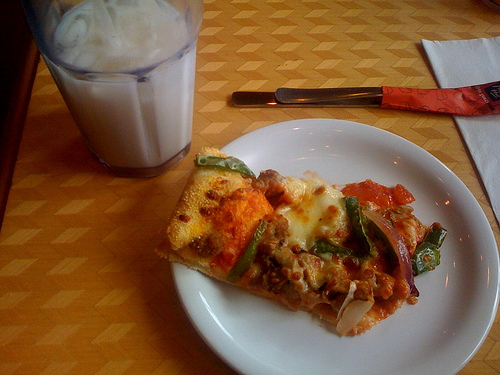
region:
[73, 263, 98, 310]
top of a table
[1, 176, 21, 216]
edge of a table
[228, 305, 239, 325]
side of a plate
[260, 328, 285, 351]
part of a plate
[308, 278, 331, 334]
part of a pizza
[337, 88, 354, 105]
part of a fork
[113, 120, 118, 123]
side of a glass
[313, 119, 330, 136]
side of a plate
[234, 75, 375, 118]
The handles to the utensils on the table.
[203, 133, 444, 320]
The green peppers on the pizza.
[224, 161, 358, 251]
The cheese on the pizza.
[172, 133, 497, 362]
The white plate the pizza is on.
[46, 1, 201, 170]
The glass on the table.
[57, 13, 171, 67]
The ice cubes in the drink.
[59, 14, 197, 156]
The milk in the cup.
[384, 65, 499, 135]
The red paper around the utensils.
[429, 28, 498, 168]
The white napkin the utensils are placed on.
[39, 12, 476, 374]
The table the items are on.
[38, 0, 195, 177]
a glass of milk with ice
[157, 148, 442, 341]
a slice of pizza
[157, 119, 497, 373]
pizza on a white plate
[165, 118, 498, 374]
a piece of pizza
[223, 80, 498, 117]
utensils wrapped in red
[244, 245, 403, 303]
a topping of meat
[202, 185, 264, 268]
a bubble of crust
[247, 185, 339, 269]
cheese on the pizza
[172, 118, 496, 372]
a white ceramic saucer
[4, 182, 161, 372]
a mosaic table top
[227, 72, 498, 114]
silverware wrapped in a red napkin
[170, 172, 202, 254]
the crust of a pizza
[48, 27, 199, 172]
a glass filled with a drink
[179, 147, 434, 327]
a piece of pizza on a plate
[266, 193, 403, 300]
the toppings on a pizza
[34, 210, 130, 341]
the design on a table top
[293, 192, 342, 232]
the melted cheese on the top of a pizza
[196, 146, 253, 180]
a green pepper on the top of a pizza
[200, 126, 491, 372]
a white plate with a piece of pizza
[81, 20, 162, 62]
the ice in a drink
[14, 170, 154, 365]
A wooden table at a restaurant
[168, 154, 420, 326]
A slice of pizza on the plate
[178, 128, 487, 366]
A white plate holding the pizza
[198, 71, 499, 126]
Eating utensils sitting on the table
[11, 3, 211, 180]
A glass of milk sitting on the table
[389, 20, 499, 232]
A white napkin sitting on the table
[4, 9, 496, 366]
A meal sitting on the table ready to eat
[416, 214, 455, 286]
A green bell pepper on the plate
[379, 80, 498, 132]
Red paper covering the eating utensils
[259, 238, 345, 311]
Sausage on the slice of the pizza